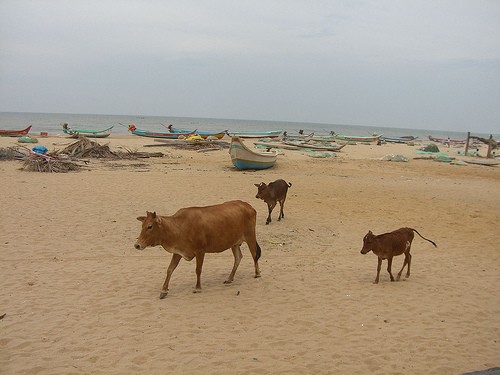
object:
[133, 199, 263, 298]
cow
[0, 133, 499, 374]
beach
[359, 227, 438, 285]
calf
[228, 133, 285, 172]
boat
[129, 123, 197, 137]
boat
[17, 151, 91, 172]
tree limbs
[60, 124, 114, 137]
boat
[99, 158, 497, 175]
tracks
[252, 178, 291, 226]
cow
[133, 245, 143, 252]
nose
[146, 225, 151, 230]
eye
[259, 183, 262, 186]
spot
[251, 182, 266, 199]
head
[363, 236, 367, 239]
spot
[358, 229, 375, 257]
head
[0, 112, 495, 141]
water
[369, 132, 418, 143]
boat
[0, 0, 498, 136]
sky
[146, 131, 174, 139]
stripe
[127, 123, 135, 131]
motor